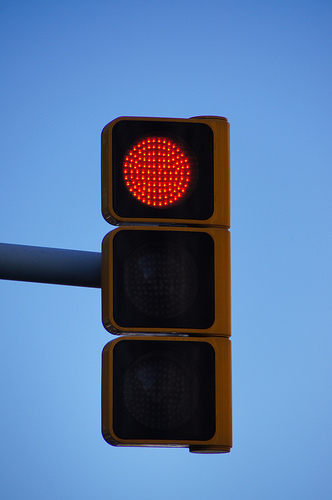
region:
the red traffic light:
[129, 138, 192, 203]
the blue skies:
[259, 291, 314, 389]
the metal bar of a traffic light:
[5, 234, 97, 295]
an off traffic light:
[119, 239, 198, 310]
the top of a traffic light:
[190, 109, 234, 123]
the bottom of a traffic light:
[187, 442, 238, 458]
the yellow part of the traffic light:
[112, 231, 224, 324]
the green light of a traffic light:
[113, 332, 219, 447]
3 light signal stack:
[112, 106, 235, 456]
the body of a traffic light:
[194, 111, 236, 455]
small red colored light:
[145, 137, 152, 144]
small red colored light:
[150, 136, 155, 143]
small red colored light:
[156, 137, 160, 144]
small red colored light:
[150, 144, 154, 149]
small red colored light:
[156, 143, 162, 150]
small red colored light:
[150, 149, 155, 156]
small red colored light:
[155, 150, 162, 156]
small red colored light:
[140, 174, 146, 178]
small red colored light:
[139, 191, 145, 196]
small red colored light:
[167, 199, 172, 203]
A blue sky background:
[21, 396, 118, 481]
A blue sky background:
[123, 467, 245, 486]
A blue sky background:
[245, 391, 329, 466]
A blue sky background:
[227, 313, 327, 383]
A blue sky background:
[237, 218, 323, 294]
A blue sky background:
[243, 108, 330, 182]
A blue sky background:
[1, 316, 87, 398]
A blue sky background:
[7, 174, 94, 229]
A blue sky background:
[9, 104, 101, 169]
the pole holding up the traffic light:
[0, 242, 102, 288]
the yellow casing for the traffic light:
[101, 114, 232, 453]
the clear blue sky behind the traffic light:
[0, 1, 331, 499]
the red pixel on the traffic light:
[158, 201, 161, 205]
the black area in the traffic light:
[111, 230, 213, 328]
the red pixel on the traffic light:
[141, 139, 145, 144]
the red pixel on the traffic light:
[186, 170, 189, 175]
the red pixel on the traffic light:
[131, 179, 134, 184]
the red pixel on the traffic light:
[126, 181, 129, 186]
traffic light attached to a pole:
[27, 40, 290, 472]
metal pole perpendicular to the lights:
[0, 221, 90, 307]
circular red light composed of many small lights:
[121, 135, 188, 203]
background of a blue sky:
[16, 9, 300, 101]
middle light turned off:
[87, 224, 234, 332]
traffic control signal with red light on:
[80, 89, 248, 447]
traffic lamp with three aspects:
[91, 99, 238, 458]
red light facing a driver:
[83, 95, 244, 459]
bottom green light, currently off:
[91, 328, 240, 465]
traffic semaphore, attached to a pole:
[78, 102, 248, 473]